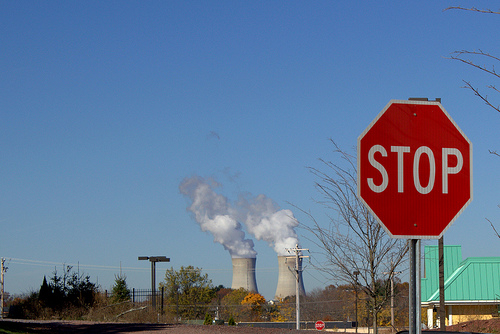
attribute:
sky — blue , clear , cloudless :
[87, 26, 281, 104]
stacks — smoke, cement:
[226, 246, 315, 293]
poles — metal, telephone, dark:
[136, 252, 171, 295]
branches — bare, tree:
[310, 160, 376, 279]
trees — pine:
[32, 266, 100, 308]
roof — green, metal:
[420, 246, 485, 295]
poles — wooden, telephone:
[286, 256, 307, 328]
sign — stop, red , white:
[353, 99, 473, 242]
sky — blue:
[64, 51, 288, 133]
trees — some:
[233, 289, 272, 316]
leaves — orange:
[230, 290, 268, 306]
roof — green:
[416, 248, 498, 305]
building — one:
[414, 253, 497, 329]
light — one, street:
[136, 246, 176, 297]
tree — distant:
[237, 287, 268, 313]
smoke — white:
[239, 189, 299, 255]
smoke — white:
[180, 174, 257, 260]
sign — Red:
[357, 99, 473, 330]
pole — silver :
[407, 238, 422, 332]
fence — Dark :
[98, 286, 163, 309]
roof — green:
[422, 256, 497, 306]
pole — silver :
[406, 237, 426, 332]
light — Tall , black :
[139, 252, 170, 308]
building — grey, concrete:
[273, 250, 303, 303]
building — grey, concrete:
[225, 252, 259, 297]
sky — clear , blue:
[4, 7, 494, 294]